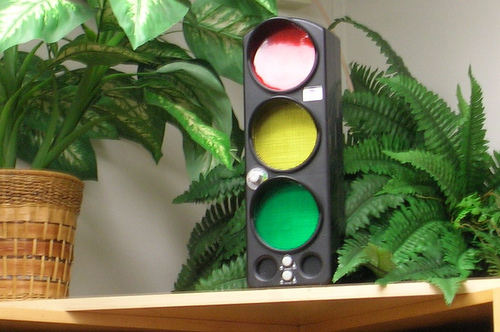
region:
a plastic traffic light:
[237, 13, 350, 291]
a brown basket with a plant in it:
[0, 0, 283, 300]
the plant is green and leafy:
[0, 0, 285, 172]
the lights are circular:
[241, 15, 349, 283]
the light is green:
[249, 176, 322, 251]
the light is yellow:
[246, 94, 321, 171]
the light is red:
[246, 18, 321, 94]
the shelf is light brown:
[0, 279, 497, 329]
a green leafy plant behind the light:
[175, 19, 499, 306]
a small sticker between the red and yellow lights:
[300, 81, 324, 103]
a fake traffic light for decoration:
[222, 17, 357, 289]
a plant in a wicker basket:
[5, 13, 209, 285]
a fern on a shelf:
[334, 26, 491, 296]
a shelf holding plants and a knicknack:
[10, 285, 496, 326]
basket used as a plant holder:
[2, 158, 86, 298]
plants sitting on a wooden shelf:
[5, 3, 493, 295]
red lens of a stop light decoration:
[265, 37, 296, 77]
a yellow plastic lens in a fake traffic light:
[267, 125, 302, 157]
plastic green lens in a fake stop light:
[262, 197, 309, 238]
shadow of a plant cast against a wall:
[102, 193, 162, 270]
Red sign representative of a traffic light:
[240, 11, 340, 87]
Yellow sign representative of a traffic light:
[240, 95, 340, 170]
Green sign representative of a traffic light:
[240, 175, 335, 250]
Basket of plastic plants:
[0, 10, 231, 292]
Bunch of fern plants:
[327, 10, 494, 301]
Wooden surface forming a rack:
[1, 272, 497, 328]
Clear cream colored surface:
[392, 18, 495, 68]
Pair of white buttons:
[280, 255, 296, 281]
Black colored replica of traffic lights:
[240, 15, 342, 287]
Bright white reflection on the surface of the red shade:
[254, 31, 314, 93]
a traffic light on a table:
[198, 16, 425, 318]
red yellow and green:
[228, 3, 408, 325]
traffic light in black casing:
[212, 13, 407, 312]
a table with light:
[135, 9, 431, 330]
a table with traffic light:
[135, 5, 464, 330]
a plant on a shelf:
[1, 8, 499, 330]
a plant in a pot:
[0, 8, 215, 330]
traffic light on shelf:
[194, 7, 480, 324]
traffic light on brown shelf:
[197, 8, 499, 297]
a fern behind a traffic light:
[173, 8, 499, 299]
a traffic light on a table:
[233, 6, 356, 286]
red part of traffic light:
[241, 19, 318, 91]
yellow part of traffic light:
[235, 94, 323, 165]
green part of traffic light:
[239, 173, 327, 258]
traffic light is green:
[236, 8, 351, 284]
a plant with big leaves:
[6, 0, 248, 180]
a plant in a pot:
[2, 1, 103, 296]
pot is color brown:
[0, 162, 90, 297]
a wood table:
[1, 283, 499, 325]